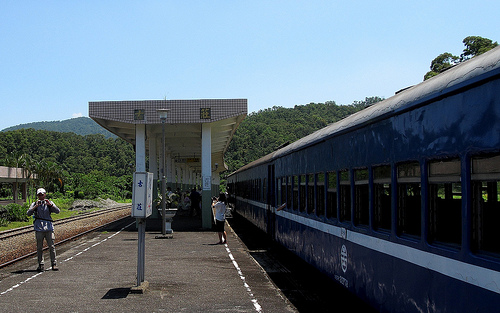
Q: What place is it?
A: It is a station.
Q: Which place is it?
A: It is a station.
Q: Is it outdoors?
A: Yes, it is outdoors.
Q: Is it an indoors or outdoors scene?
A: It is outdoors.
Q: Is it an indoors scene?
A: No, it is outdoors.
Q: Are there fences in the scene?
A: No, there are no fences.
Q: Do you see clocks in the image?
A: No, there are no clocks.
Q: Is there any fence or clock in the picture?
A: No, there are no clocks or fences.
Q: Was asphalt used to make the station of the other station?
A: Yes, the station is made of asphalt.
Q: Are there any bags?
A: No, there are no bags.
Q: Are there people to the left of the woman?
A: Yes, there is a person to the left of the woman.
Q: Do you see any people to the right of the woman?
A: No, the person is to the left of the woman.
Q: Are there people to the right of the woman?
A: No, the person is to the left of the woman.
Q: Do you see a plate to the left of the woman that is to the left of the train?
A: No, there is a person to the left of the woman.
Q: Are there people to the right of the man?
A: Yes, there is a person to the right of the man.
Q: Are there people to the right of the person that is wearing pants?
A: Yes, there is a person to the right of the man.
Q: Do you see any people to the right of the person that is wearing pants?
A: Yes, there is a person to the right of the man.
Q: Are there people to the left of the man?
A: No, the person is to the right of the man.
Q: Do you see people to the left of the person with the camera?
A: No, the person is to the right of the man.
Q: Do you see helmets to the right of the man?
A: No, there is a person to the right of the man.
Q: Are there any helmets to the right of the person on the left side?
A: No, there is a person to the right of the man.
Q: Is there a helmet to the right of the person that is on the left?
A: No, there is a person to the right of the man.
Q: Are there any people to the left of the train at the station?
A: Yes, there is a person to the left of the train.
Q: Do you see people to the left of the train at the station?
A: Yes, there is a person to the left of the train.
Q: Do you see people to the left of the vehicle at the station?
A: Yes, there is a person to the left of the train.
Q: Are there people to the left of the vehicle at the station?
A: Yes, there is a person to the left of the train.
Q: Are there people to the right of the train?
A: No, the person is to the left of the train.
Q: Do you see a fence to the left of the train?
A: No, there is a person to the left of the train.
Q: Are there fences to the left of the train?
A: No, there is a person to the left of the train.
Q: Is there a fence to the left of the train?
A: No, there is a person to the left of the train.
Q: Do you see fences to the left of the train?
A: No, there is a person to the left of the train.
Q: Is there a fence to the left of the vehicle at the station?
A: No, there is a person to the left of the train.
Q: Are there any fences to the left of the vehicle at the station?
A: No, there is a person to the left of the train.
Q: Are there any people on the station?
A: Yes, there is a person on the station.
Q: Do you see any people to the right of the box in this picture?
A: Yes, there is a person to the right of the box.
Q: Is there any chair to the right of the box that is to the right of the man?
A: No, there is a person to the right of the box.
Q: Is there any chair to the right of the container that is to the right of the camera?
A: No, there is a person to the right of the box.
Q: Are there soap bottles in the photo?
A: No, there are no soap bottles.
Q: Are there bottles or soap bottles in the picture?
A: No, there are no soap bottles or bottles.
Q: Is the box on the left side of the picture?
A: Yes, the box is on the left of the image.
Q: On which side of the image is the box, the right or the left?
A: The box is on the left of the image.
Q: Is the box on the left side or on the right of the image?
A: The box is on the left of the image.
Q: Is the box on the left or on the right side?
A: The box is on the left of the image.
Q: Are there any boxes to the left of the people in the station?
A: Yes, there is a box to the left of the people.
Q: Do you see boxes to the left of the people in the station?
A: Yes, there is a box to the left of the people.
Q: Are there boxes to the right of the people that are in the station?
A: No, the box is to the left of the people.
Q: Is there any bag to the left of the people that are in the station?
A: No, there is a box to the left of the people.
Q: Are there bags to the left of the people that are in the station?
A: No, there is a box to the left of the people.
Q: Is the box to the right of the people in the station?
A: No, the box is to the left of the people.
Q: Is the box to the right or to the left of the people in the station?
A: The box is to the left of the people.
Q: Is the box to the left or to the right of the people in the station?
A: The box is to the left of the people.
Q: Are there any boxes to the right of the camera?
A: Yes, there is a box to the right of the camera.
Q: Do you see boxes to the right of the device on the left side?
A: Yes, there is a box to the right of the camera.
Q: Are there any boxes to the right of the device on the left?
A: Yes, there is a box to the right of the camera.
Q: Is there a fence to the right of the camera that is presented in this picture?
A: No, there is a box to the right of the camera.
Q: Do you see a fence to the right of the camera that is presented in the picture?
A: No, there is a box to the right of the camera.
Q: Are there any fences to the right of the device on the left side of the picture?
A: No, there is a box to the right of the camera.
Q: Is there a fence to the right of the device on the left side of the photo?
A: No, there is a box to the right of the camera.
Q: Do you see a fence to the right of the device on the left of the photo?
A: No, there is a box to the right of the camera.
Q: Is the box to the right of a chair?
A: No, the box is to the right of the camera.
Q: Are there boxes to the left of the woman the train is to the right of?
A: Yes, there is a box to the left of the woman.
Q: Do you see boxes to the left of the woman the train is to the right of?
A: Yes, there is a box to the left of the woman.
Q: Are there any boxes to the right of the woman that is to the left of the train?
A: No, the box is to the left of the woman.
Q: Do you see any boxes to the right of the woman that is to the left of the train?
A: No, the box is to the left of the woman.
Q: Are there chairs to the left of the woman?
A: No, there is a box to the left of the woman.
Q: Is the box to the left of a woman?
A: Yes, the box is to the left of a woman.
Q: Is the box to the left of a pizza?
A: No, the box is to the left of a woman.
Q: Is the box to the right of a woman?
A: No, the box is to the left of a woman.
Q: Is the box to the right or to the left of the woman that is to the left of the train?
A: The box is to the left of the woman.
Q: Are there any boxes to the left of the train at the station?
A: Yes, there is a box to the left of the train.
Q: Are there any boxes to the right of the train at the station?
A: No, the box is to the left of the train.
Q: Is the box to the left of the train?
A: Yes, the box is to the left of the train.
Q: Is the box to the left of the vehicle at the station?
A: Yes, the box is to the left of the train.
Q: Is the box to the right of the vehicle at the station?
A: No, the box is to the left of the train.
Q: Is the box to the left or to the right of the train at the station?
A: The box is to the left of the train.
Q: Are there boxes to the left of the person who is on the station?
A: Yes, there is a box to the left of the person.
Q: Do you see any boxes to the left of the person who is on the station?
A: Yes, there is a box to the left of the person.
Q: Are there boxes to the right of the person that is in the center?
A: No, the box is to the left of the person.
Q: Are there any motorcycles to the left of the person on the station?
A: No, there is a box to the left of the person.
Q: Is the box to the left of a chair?
A: No, the box is to the left of the person.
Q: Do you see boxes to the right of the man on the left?
A: Yes, there is a box to the right of the man.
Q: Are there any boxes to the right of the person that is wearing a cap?
A: Yes, there is a box to the right of the man.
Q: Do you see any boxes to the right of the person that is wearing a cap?
A: Yes, there is a box to the right of the man.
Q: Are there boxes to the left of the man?
A: No, the box is to the right of the man.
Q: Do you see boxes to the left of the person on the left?
A: No, the box is to the right of the man.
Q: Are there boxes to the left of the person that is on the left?
A: No, the box is to the right of the man.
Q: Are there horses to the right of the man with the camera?
A: No, there is a box to the right of the man.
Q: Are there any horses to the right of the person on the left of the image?
A: No, there is a box to the right of the man.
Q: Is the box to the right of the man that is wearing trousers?
A: Yes, the box is to the right of the man.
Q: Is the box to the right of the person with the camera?
A: Yes, the box is to the right of the man.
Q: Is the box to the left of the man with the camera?
A: No, the box is to the right of the man.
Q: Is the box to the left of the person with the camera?
A: No, the box is to the right of the man.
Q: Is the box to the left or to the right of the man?
A: The box is to the right of the man.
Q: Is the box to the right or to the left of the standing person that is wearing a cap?
A: The box is to the right of the man.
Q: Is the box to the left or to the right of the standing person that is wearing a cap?
A: The box is to the right of the man.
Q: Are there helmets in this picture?
A: No, there are no helmets.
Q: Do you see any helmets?
A: No, there are no helmets.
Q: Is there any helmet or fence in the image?
A: No, there are no helmets or fences.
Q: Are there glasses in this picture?
A: No, there are no glasses.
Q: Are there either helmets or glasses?
A: No, there are no glasses or helmets.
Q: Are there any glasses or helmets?
A: No, there are no glasses or helmets.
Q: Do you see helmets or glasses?
A: No, there are no glasses or helmets.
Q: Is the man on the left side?
A: Yes, the man is on the left of the image.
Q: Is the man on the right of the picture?
A: No, the man is on the left of the image.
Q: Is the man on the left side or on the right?
A: The man is on the left of the image.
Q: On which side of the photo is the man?
A: The man is on the left of the image.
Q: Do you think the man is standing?
A: Yes, the man is standing.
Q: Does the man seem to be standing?
A: Yes, the man is standing.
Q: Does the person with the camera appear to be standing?
A: Yes, the man is standing.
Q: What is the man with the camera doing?
A: The man is standing.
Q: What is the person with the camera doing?
A: The man is standing.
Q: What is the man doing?
A: The man is standing.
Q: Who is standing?
A: The man is standing.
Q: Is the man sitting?
A: No, the man is standing.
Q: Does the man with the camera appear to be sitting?
A: No, the man is standing.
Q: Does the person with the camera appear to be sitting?
A: No, the man is standing.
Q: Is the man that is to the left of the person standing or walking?
A: The man is standing.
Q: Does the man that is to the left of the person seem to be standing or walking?
A: The man is standing.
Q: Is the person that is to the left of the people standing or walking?
A: The man is standing.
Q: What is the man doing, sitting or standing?
A: The man is standing.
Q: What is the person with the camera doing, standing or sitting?
A: The man is standing.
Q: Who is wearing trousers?
A: The man is wearing trousers.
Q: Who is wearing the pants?
A: The man is wearing trousers.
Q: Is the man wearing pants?
A: Yes, the man is wearing pants.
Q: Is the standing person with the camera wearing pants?
A: Yes, the man is wearing pants.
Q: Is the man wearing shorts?
A: No, the man is wearing pants.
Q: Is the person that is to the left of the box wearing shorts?
A: No, the man is wearing pants.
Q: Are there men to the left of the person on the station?
A: Yes, there is a man to the left of the person.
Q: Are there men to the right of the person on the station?
A: No, the man is to the left of the person.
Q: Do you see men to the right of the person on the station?
A: No, the man is to the left of the person.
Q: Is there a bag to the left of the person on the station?
A: No, there is a man to the left of the person.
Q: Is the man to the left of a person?
A: Yes, the man is to the left of a person.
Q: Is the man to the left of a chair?
A: No, the man is to the left of a person.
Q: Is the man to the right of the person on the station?
A: No, the man is to the left of the person.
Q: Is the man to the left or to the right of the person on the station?
A: The man is to the left of the person.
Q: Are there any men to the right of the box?
A: No, the man is to the left of the box.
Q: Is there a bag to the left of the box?
A: No, there is a man to the left of the box.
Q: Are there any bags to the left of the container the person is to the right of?
A: No, there is a man to the left of the box.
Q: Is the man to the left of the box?
A: Yes, the man is to the left of the box.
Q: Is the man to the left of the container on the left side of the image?
A: Yes, the man is to the left of the box.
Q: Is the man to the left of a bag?
A: No, the man is to the left of the box.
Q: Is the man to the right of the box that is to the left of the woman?
A: No, the man is to the left of the box.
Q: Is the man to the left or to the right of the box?
A: The man is to the left of the box.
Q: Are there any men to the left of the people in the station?
A: Yes, there is a man to the left of the people.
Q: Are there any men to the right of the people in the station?
A: No, the man is to the left of the people.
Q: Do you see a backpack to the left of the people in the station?
A: No, there is a man to the left of the people.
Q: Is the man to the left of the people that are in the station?
A: Yes, the man is to the left of the people.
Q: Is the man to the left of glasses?
A: No, the man is to the left of the people.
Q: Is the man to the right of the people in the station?
A: No, the man is to the left of the people.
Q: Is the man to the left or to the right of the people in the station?
A: The man is to the left of the people.